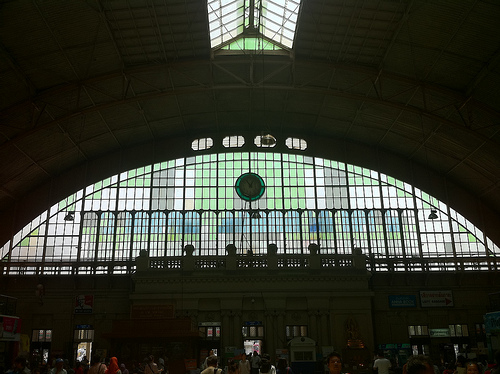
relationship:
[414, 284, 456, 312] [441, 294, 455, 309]
advertisement sign has arrow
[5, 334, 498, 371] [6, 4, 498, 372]
crowd at station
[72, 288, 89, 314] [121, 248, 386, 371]
advertisement for restaraunt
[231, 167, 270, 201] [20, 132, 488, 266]
clock on wall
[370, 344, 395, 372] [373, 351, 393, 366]
man in shirt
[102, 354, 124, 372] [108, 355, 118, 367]
woman with head covering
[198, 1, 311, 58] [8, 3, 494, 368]
skylight in building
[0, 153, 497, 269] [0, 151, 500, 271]
half circle of glass doorway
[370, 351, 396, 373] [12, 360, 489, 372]
man standing in line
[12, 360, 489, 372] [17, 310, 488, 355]
line at counters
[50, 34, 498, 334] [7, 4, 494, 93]
building has roof